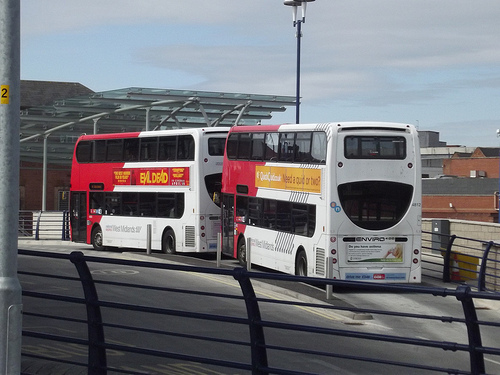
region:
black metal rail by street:
[171, 250, 263, 352]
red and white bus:
[230, 137, 346, 233]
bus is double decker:
[232, 138, 395, 324]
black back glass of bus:
[340, 181, 401, 241]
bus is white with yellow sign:
[252, 165, 323, 202]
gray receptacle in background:
[430, 216, 450, 246]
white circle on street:
[95, 265, 145, 290]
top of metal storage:
[110, 90, 140, 126]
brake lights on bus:
[325, 235, 355, 282]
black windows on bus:
[95, 149, 188, 170]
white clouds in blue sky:
[30, 2, 102, 37]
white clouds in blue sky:
[25, 36, 80, 73]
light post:
[286, 5, 306, 25]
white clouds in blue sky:
[441, 32, 491, 125]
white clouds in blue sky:
[80, 35, 130, 72]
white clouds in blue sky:
[172, 15, 250, 53]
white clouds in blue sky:
[165, 37, 268, 75]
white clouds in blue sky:
[341, 18, 459, 51]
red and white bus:
[81, 115, 218, 258]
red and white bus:
[222, 121, 407, 294]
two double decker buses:
[66, 123, 436, 305]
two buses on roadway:
[52, 118, 437, 290]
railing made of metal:
[53, 246, 498, 364]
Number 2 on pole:
[0, 80, 16, 117]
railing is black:
[46, 273, 485, 368]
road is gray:
[69, 240, 288, 347]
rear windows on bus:
[343, 131, 411, 162]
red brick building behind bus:
[427, 190, 496, 220]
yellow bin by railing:
[444, 242, 479, 290]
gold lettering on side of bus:
[106, 162, 201, 190]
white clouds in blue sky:
[33, 7, 100, 61]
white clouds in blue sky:
[98, 21, 182, 71]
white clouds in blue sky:
[217, 2, 263, 83]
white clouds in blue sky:
[157, 11, 228, 91]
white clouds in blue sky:
[336, 4, 372, 100]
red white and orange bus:
[65, 120, 198, 258]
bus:
[273, 133, 417, 281]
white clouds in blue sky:
[320, 21, 364, 110]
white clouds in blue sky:
[390, 2, 436, 127]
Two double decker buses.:
[58, 95, 435, 292]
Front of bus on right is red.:
[215, 115, 430, 295]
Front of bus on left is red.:
[61, 122, 220, 259]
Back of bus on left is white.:
[76, 126, 225, 255]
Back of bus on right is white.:
[228, 124, 428, 286]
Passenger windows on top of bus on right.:
[228, 129, 328, 170]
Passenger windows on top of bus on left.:
[70, 130, 198, 166]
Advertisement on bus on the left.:
[108, 163, 189, 193]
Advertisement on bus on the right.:
[249, 160, 326, 194]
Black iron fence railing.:
[17, 219, 498, 374]